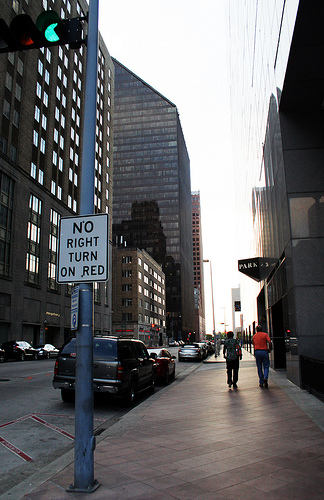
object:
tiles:
[85, 375, 323, 498]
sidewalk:
[1, 363, 324, 499]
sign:
[57, 214, 110, 282]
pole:
[67, 0, 99, 487]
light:
[44, 21, 62, 42]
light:
[116, 365, 125, 380]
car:
[52, 334, 157, 406]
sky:
[99, 0, 233, 214]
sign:
[237, 257, 277, 283]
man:
[253, 325, 272, 389]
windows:
[27, 45, 84, 202]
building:
[0, 0, 113, 342]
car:
[146, 347, 177, 386]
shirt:
[252, 331, 270, 350]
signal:
[0, 13, 81, 48]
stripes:
[0, 414, 70, 479]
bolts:
[67, 15, 79, 43]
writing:
[45, 310, 60, 317]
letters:
[60, 220, 105, 278]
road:
[1, 337, 219, 500]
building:
[221, 0, 324, 396]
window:
[118, 342, 148, 360]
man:
[223, 331, 242, 388]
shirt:
[224, 338, 242, 362]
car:
[178, 343, 201, 362]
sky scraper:
[109, 49, 194, 342]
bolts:
[66, 478, 101, 500]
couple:
[223, 324, 273, 388]